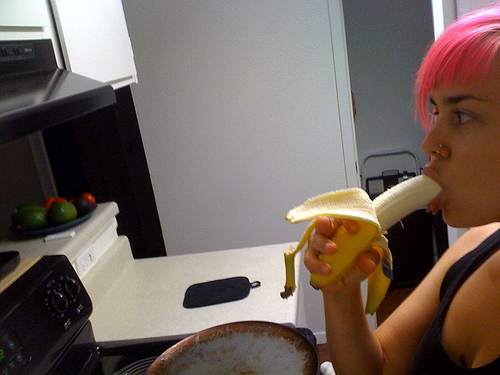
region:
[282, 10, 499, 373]
girl with pink air eating a banana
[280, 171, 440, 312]
a banana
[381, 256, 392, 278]
blue sticker on the banana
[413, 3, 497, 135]
the girl's pink hair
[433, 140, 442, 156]
the girl's nose ring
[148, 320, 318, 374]
a pan on top of the stove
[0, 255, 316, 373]
a black stove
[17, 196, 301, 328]
white counter next to the stove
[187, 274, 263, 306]
a black pot holder on the counter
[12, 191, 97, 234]
vegetables on a plate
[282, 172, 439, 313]
A banana in the woman's right hand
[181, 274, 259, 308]
An oven mitt on the counter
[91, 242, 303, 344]
The counter next to the stove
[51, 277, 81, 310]
Buttons on the stove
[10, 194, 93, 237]
Fruit on the tray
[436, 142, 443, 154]
The woman is wearing a nose ring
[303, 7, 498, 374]
A woman standing next to a stove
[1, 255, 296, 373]
A stove next to the counter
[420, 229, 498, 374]
The woman is wearing a black shirt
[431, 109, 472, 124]
The eyes of the woman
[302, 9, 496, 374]
a girl with bright pink hair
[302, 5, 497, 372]
a young woman eating a banana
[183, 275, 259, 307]
a square black potholder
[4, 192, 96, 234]
a tray full of fruit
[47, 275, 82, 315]
two black oven knobs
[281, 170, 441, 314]
a peeled ripe banana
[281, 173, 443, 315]
a peeled banana with a blue sticket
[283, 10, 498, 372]
a young woman with a nose piercing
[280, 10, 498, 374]
a young woman wearing a black shirt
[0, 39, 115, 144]
a black range hood above the stove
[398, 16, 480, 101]
her hair is pink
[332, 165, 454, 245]
eating a yellow banana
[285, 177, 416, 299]
the banana is half pealed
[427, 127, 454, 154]
the nose ring is silver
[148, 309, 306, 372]
the pan is dirty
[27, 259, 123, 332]
the stove dials are black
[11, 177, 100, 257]
fruits on a plate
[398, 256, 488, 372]
wearing a black shirt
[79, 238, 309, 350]
the counter is white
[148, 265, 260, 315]
the pot holder is black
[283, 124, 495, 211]
the woman is eating a banana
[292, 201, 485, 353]
the banana is yellow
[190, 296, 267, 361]
the pan is rusted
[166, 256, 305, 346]
a mitt is on the counter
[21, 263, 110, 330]
the stove is black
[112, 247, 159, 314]
the counter is white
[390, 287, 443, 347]
the woman is wearing a black top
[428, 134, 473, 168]
the woman has a pierced nose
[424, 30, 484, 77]
the woman has pink hair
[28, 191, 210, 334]
fruit is on the counter